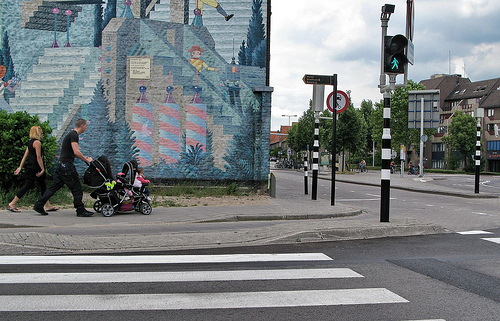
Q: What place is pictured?
A: It is a street.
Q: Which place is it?
A: It is a street.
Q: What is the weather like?
A: It is overcast.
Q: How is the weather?
A: It is overcast.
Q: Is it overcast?
A: Yes, it is overcast.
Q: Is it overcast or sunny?
A: It is overcast.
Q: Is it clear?
A: No, it is overcast.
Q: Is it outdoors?
A: Yes, it is outdoors.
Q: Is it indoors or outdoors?
A: It is outdoors.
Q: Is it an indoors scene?
A: No, it is outdoors.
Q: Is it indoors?
A: No, it is outdoors.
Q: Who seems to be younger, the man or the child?
A: The child is younger than the man.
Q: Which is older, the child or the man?
A: The man is older than the child.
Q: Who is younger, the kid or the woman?
A: The kid is younger than the woman.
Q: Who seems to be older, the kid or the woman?
A: The woman is older than the kid.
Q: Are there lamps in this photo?
A: No, there are no lamps.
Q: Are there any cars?
A: No, there are no cars.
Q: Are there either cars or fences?
A: No, there are no cars or fences.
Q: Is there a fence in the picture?
A: No, there are no fences.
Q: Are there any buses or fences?
A: No, there are no fences or buses.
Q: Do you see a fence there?
A: No, there are no fences.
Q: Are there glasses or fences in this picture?
A: No, there are no fences or glasses.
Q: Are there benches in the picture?
A: No, there are no benches.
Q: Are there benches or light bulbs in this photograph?
A: No, there are no benches or light bulbs.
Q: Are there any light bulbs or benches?
A: No, there are no benches or light bulbs.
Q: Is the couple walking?
A: Yes, the couple is walking.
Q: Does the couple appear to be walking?
A: Yes, the couple is walking.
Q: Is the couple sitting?
A: No, the couple is walking.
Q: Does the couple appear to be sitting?
A: No, the couple is walking.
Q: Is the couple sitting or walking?
A: The couple is walking.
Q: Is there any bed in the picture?
A: No, there are no beds.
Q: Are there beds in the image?
A: No, there are no beds.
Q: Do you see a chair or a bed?
A: No, there are no beds or chairs.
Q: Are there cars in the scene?
A: No, there are no cars.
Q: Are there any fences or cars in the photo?
A: No, there are no cars or fences.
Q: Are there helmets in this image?
A: No, there are no helmets.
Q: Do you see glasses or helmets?
A: No, there are no helmets or glasses.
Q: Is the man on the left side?
A: Yes, the man is on the left of the image.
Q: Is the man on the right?
A: No, the man is on the left of the image.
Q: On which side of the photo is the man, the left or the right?
A: The man is on the left of the image.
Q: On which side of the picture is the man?
A: The man is on the left of the image.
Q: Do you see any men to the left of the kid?
A: Yes, there is a man to the left of the kid.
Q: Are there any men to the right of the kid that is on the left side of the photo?
A: No, the man is to the left of the kid.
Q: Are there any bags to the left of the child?
A: No, there is a man to the left of the child.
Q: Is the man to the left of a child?
A: Yes, the man is to the left of a child.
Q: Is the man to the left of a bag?
A: No, the man is to the left of a child.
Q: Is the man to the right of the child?
A: No, the man is to the left of the child.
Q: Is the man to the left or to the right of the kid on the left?
A: The man is to the left of the child.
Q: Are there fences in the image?
A: No, there are no fences.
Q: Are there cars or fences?
A: No, there are no fences or cars.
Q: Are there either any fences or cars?
A: No, there are no fences or cars.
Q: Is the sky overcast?
A: Yes, the sky is overcast.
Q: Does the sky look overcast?
A: Yes, the sky is overcast.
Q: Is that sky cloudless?
A: No, the sky is overcast.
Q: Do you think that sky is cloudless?
A: No, the sky is overcast.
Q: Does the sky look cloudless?
A: No, the sky is overcast.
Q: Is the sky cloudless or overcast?
A: The sky is overcast.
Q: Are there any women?
A: Yes, there is a woman.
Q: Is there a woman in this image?
A: Yes, there is a woman.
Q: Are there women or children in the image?
A: Yes, there is a woman.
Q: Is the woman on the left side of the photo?
A: Yes, the woman is on the left of the image.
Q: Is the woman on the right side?
A: No, the woman is on the left of the image.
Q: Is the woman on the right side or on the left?
A: The woman is on the left of the image.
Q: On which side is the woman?
A: The woman is on the left of the image.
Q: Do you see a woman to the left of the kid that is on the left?
A: Yes, there is a woman to the left of the kid.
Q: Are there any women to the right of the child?
A: No, the woman is to the left of the child.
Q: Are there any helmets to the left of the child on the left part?
A: No, there is a woman to the left of the kid.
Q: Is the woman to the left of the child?
A: Yes, the woman is to the left of the child.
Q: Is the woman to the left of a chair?
A: No, the woman is to the left of the child.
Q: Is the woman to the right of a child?
A: No, the woman is to the left of a child.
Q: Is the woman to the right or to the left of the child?
A: The woman is to the left of the child.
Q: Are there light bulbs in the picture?
A: No, there are no light bulbs.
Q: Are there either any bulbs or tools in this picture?
A: No, there are no bulbs or tools.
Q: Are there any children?
A: Yes, there is a child.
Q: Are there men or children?
A: Yes, there is a child.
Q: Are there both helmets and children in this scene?
A: No, there is a child but no helmets.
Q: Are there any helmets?
A: No, there are no helmets.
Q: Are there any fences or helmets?
A: No, there are no helmets or fences.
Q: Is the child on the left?
A: Yes, the child is on the left of the image.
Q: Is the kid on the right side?
A: No, the kid is on the left of the image.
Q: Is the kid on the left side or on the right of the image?
A: The kid is on the left of the image.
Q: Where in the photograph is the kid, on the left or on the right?
A: The kid is on the left of the image.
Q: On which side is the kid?
A: The kid is on the left of the image.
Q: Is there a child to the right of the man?
A: Yes, there is a child to the right of the man.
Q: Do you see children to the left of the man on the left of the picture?
A: No, the child is to the right of the man.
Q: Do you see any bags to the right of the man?
A: No, there is a child to the right of the man.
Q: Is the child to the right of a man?
A: Yes, the child is to the right of a man.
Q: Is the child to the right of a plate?
A: No, the child is to the right of a man.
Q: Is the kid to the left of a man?
A: No, the kid is to the right of a man.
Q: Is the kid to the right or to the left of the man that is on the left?
A: The kid is to the right of the man.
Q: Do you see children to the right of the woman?
A: Yes, there is a child to the right of the woman.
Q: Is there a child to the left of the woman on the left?
A: No, the child is to the right of the woman.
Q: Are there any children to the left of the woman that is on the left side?
A: No, the child is to the right of the woman.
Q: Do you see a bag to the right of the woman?
A: No, there is a child to the right of the woman.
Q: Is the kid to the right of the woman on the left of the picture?
A: Yes, the kid is to the right of the woman.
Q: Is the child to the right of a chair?
A: No, the child is to the right of the woman.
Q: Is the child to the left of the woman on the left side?
A: No, the child is to the right of the woman.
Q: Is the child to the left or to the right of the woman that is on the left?
A: The child is to the right of the woman.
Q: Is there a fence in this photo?
A: No, there are no fences.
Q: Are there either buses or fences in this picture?
A: No, there are no fences or buses.